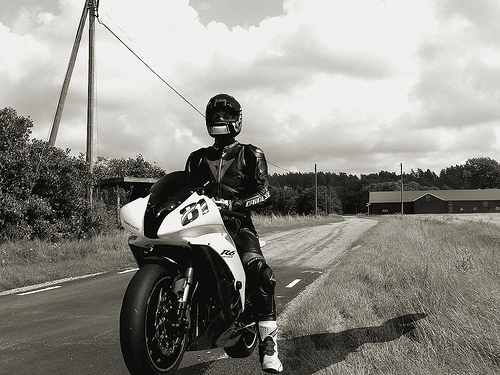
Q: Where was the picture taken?
A: It was taken at the road.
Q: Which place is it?
A: It is a road.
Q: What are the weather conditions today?
A: It is cloudy.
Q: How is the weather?
A: It is cloudy.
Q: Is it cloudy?
A: Yes, it is cloudy.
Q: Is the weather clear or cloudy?
A: It is cloudy.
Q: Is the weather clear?
A: No, it is cloudy.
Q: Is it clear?
A: No, it is cloudy.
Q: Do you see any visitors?
A: No, there are no visitors.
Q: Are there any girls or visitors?
A: No, there are no visitors or girls.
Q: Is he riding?
A: Yes, the man is riding.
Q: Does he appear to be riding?
A: Yes, the man is riding.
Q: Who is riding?
A: The man is riding.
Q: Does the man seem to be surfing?
A: No, the man is riding.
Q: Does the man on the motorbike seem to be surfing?
A: No, the man is riding.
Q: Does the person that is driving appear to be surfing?
A: No, the man is riding.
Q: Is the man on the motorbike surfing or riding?
A: The man is riding.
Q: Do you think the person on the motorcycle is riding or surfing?
A: The man is riding.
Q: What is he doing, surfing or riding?
A: The man is riding.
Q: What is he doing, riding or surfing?
A: The man is riding.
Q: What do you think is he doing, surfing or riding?
A: The man is riding.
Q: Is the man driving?
A: Yes, the man is driving.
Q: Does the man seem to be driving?
A: Yes, the man is driving.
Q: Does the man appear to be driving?
A: Yes, the man is driving.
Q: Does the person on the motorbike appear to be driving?
A: Yes, the man is driving.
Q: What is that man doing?
A: The man is driving.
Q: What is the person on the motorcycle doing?
A: The man is driving.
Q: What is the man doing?
A: The man is driving.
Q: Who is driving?
A: The man is driving.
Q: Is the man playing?
A: No, the man is driving.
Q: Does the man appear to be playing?
A: No, the man is driving.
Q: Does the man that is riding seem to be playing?
A: No, the man is driving.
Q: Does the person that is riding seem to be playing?
A: No, the man is driving.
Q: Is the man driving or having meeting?
A: The man is driving.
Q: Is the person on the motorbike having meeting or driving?
A: The man is driving.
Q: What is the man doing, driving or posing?
A: The man is driving.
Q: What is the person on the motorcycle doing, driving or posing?
A: The man is driving.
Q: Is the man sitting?
A: Yes, the man is sitting.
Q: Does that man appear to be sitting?
A: Yes, the man is sitting.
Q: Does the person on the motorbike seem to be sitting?
A: Yes, the man is sitting.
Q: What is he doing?
A: The man is sitting.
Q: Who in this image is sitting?
A: The man is sitting.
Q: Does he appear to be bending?
A: No, the man is sitting.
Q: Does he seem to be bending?
A: No, the man is sitting.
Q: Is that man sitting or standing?
A: The man is sitting.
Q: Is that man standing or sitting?
A: The man is sitting.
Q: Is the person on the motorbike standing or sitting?
A: The man is sitting.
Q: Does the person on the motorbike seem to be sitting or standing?
A: The man is sitting.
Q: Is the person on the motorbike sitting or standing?
A: The man is sitting.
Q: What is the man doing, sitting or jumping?
A: The man is sitting.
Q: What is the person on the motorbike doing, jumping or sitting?
A: The man is sitting.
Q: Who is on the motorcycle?
A: The man is on the motorcycle.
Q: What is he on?
A: The man is on the motorcycle.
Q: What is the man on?
A: The man is on the motorcycle.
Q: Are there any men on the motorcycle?
A: Yes, there is a man on the motorcycle.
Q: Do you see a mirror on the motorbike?
A: No, there is a man on the motorbike.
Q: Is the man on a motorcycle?
A: Yes, the man is on a motorcycle.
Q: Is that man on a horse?
A: No, the man is on a motorcycle.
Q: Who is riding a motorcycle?
A: The man is riding a motorcycle.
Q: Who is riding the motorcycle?
A: The man is riding a motorcycle.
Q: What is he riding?
A: The man is riding a motorcycle.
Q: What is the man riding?
A: The man is riding a motorcycle.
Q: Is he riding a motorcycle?
A: Yes, the man is riding a motorcycle.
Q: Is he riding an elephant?
A: No, the man is riding a motorcycle.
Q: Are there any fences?
A: No, there are no fences.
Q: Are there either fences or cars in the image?
A: No, there are no fences or cars.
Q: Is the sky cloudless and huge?
A: No, the sky is huge but cloudy.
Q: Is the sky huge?
A: Yes, the sky is huge.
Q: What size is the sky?
A: The sky is huge.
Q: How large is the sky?
A: The sky is huge.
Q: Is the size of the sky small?
A: No, the sky is huge.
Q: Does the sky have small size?
A: No, the sky is huge.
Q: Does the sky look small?
A: No, the sky is huge.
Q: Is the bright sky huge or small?
A: The sky is huge.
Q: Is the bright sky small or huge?
A: The sky is huge.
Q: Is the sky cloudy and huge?
A: Yes, the sky is cloudy and huge.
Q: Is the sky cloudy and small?
A: No, the sky is cloudy but huge.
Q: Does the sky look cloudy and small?
A: No, the sky is cloudy but huge.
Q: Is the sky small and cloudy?
A: No, the sky is cloudy but huge.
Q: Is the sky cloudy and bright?
A: Yes, the sky is cloudy and bright.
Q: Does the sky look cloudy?
A: Yes, the sky is cloudy.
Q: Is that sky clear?
A: No, the sky is cloudy.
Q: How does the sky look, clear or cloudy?
A: The sky is cloudy.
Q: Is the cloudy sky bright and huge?
A: Yes, the sky is bright and huge.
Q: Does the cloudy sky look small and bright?
A: No, the sky is bright but huge.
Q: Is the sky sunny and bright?
A: No, the sky is bright but cloudy.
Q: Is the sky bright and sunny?
A: No, the sky is bright but cloudy.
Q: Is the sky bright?
A: Yes, the sky is bright.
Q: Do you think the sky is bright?
A: Yes, the sky is bright.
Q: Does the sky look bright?
A: Yes, the sky is bright.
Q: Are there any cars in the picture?
A: No, there are no cars.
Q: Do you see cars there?
A: No, there are no cars.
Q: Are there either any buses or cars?
A: No, there are no cars or buses.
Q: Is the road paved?
A: Yes, the road is paved.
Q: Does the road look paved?
A: Yes, the road is paved.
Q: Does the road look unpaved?
A: No, the road is paved.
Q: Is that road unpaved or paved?
A: The road is paved.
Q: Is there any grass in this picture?
A: Yes, there is grass.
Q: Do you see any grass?
A: Yes, there is grass.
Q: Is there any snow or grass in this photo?
A: Yes, there is grass.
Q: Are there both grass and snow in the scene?
A: No, there is grass but no snow.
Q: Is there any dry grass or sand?
A: Yes, there is dry grass.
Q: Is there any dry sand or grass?
A: Yes, there is dry grass.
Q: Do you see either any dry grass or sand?
A: Yes, there is dry grass.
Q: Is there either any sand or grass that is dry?
A: Yes, the grass is dry.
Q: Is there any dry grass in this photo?
A: Yes, there is dry grass.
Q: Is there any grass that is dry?
A: Yes, there is grass that is dry.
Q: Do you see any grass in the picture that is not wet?
A: Yes, there is dry grass.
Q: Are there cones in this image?
A: No, there are no cones.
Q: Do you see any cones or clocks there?
A: No, there are no cones or clocks.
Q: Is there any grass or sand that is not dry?
A: No, there is grass but it is dry.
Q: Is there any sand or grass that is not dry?
A: No, there is grass but it is dry.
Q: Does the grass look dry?
A: Yes, the grass is dry.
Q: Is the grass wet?
A: No, the grass is dry.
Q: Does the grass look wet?
A: No, the grass is dry.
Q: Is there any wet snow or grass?
A: No, there is grass but it is dry.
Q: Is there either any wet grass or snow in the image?
A: No, there is grass but it is dry.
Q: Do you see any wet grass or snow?
A: No, there is grass but it is dry.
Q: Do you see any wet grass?
A: No, there is grass but it is dry.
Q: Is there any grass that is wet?
A: No, there is grass but it is dry.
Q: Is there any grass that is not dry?
A: No, there is grass but it is dry.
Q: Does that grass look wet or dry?
A: The grass is dry.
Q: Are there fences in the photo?
A: No, there are no fences.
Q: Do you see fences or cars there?
A: No, there are no fences or cars.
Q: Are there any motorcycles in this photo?
A: Yes, there is a motorcycle.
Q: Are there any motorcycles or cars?
A: Yes, there is a motorcycle.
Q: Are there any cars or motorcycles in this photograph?
A: Yes, there is a motorcycle.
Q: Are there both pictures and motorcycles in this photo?
A: No, there is a motorcycle but no pictures.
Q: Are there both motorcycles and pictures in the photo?
A: No, there is a motorcycle but no pictures.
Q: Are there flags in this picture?
A: No, there are no flags.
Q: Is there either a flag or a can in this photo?
A: No, there are no flags or cans.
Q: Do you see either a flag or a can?
A: No, there are no flags or cans.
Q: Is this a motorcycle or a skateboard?
A: This is a motorcycle.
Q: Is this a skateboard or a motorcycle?
A: This is a motorcycle.